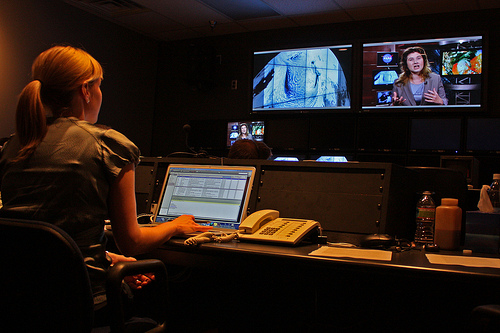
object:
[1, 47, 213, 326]
person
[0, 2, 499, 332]
building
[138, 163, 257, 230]
laptop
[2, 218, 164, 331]
chair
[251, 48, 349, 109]
screen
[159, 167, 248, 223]
monitor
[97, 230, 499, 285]
desk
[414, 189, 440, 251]
bottle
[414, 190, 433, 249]
water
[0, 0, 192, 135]
wall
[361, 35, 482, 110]
tv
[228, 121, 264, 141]
monitor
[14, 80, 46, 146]
tail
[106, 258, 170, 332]
arm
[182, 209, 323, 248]
phone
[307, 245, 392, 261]
paper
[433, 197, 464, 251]
bottle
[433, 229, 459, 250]
liquid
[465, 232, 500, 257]
box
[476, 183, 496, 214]
tissue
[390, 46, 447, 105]
woman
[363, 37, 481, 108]
screen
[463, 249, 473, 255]
cap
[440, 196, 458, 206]
cap